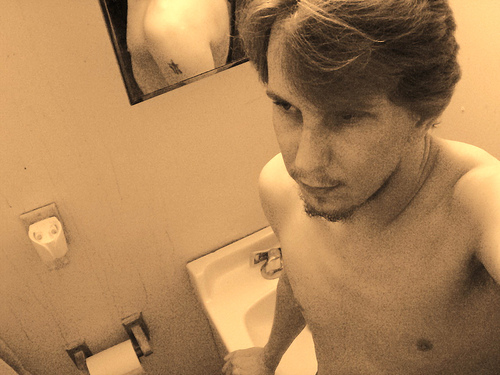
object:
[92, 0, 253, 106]
mirror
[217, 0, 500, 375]
man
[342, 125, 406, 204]
cheek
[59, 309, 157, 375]
holder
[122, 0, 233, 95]
man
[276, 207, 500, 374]
chest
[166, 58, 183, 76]
tattoo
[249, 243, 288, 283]
faucet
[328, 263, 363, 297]
chest`s part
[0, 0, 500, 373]
bathroom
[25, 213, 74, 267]
tissue paper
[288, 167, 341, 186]
mustache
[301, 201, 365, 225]
goatee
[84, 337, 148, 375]
toilet paper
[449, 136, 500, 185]
shoulder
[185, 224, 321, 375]
sink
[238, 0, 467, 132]
hair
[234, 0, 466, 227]
head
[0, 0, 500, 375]
wall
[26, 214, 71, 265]
dispenser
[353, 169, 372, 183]
part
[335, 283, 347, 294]
part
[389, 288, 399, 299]
part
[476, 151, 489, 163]
part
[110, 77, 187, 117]
corner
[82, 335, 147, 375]
roll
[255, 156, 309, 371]
arm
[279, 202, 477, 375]
chested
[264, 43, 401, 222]
face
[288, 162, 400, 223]
beard